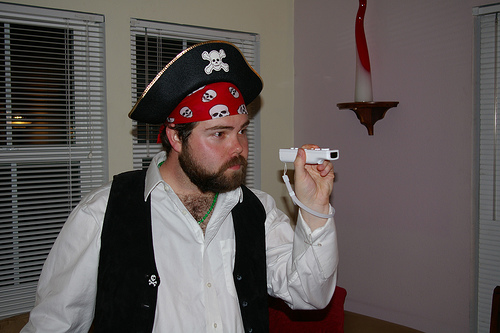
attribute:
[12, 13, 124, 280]
blinds — long, white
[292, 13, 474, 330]
wall — painted, purple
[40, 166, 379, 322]
shirt — white, long sleeve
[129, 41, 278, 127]
hat — black, gold, white, pirate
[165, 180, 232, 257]
necklace — green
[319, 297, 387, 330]
carpet — indoor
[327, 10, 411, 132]
statue — tall, white, red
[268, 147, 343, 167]
console remote — gaming, wii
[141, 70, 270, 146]
bandana — red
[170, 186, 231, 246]
necklace — green, beaded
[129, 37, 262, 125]
pirates hat — black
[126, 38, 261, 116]
trim — gold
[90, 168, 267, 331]
vest — black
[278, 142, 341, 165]
game controller — white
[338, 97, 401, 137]
shelf — small